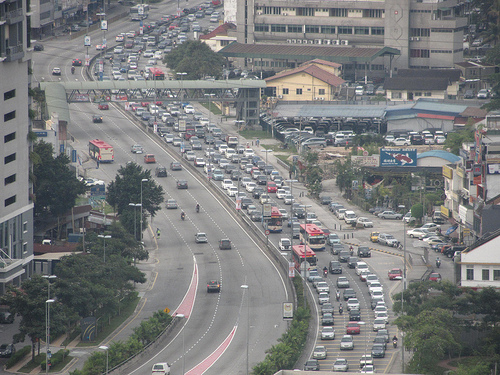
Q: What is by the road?
A: A building.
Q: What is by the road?
A: A house.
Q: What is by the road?
A: Green trees.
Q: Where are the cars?
A: On the road.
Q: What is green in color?
A: The trees.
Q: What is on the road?
A: Traffic.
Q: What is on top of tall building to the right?
A: A restaurant sign.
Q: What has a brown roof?
A: A tan house.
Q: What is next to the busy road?
A: A restaurant.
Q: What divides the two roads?
A: A concrete divider.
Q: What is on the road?
A: Many cars.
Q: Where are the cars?
A: On the road.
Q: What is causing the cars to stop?
A: Traffic jam.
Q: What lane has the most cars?
A: Lane on the right.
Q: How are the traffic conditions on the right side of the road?
A: Traffic is jammed.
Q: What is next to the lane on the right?
A: Buildings.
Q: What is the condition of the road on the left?
A: Clear.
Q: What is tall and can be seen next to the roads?
A: Buildings.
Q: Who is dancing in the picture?
A: No one.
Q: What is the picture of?
A: Traffic in a big city.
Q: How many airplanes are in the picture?
A: None.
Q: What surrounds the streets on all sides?
A: Buildings.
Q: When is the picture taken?
A: Daytime.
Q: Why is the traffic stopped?
A: Traffic Jam.